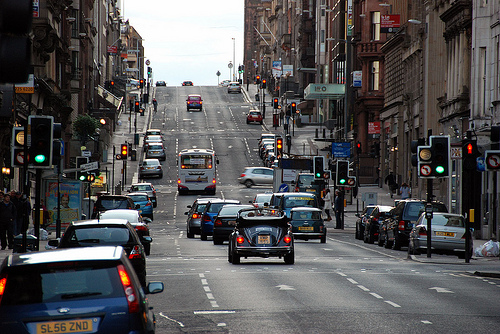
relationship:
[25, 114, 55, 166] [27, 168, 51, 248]
stoplight on pole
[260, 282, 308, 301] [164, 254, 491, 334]
arrow on road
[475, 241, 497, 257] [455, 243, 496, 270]
trashbag on curb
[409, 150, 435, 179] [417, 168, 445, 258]
light on pole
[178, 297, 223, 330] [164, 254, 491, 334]
manhole on road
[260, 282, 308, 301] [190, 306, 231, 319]
arrow has line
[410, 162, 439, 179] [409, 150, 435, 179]
sign near light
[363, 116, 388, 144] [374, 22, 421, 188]
sign on buillding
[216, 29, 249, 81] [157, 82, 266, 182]
post on hill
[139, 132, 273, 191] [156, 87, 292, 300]
cars on street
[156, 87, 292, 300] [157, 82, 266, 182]
street on hill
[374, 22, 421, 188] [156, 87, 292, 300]
buillding on street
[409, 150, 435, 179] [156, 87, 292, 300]
light on street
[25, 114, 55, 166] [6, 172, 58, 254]
stoplight on corner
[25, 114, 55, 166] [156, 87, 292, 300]
stoplight on street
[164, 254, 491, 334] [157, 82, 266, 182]
road on hill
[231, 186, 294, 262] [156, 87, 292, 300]
car on street